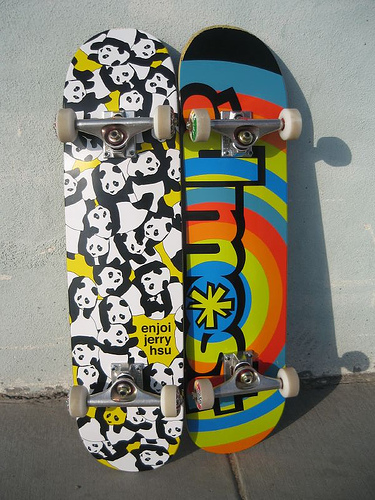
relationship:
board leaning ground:
[55, 25, 186, 473] [13, 391, 349, 498]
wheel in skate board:
[186, 107, 210, 143] [174, 15, 326, 455]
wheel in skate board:
[275, 100, 311, 145] [174, 15, 326, 455]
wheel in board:
[52, 102, 87, 147] [55, 25, 186, 473]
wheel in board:
[153, 104, 172, 140] [55, 25, 186, 473]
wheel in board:
[69, 385, 88, 418] [55, 25, 186, 473]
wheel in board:
[161, 384, 179, 416] [55, 25, 186, 473]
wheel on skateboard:
[277, 364, 300, 398] [183, 23, 289, 453]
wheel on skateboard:
[278, 107, 302, 140] [183, 23, 289, 453]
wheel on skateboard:
[186, 107, 210, 143] [183, 23, 289, 453]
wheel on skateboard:
[161, 384, 179, 416] [56, 27, 182, 471]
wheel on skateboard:
[152, 101, 173, 140] [56, 27, 182, 471]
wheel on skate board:
[184, 106, 211, 143] [175, 23, 290, 455]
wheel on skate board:
[278, 107, 302, 140] [175, 23, 290, 455]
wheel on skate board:
[193, 379, 214, 411] [175, 23, 290, 455]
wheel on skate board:
[277, 364, 300, 398] [175, 23, 290, 455]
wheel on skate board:
[153, 104, 172, 140] [60, 26, 189, 474]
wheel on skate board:
[55, 108, 77, 141] [60, 26, 189, 474]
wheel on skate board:
[69, 385, 88, 418] [60, 26, 189, 474]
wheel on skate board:
[157, 382, 182, 417] [60, 26, 189, 474]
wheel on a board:
[55, 108, 77, 141] [55, 25, 186, 473]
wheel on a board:
[153, 104, 172, 140] [55, 25, 186, 473]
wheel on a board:
[68, 385, 89, 421] [55, 25, 186, 473]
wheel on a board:
[161, 384, 179, 416] [55, 25, 186, 473]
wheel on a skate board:
[186, 107, 210, 143] [177, 26, 302, 455]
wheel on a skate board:
[278, 107, 302, 140] [177, 26, 302, 455]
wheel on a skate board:
[192, 375, 213, 413] [177, 26, 302, 455]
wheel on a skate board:
[275, 365, 298, 397] [177, 26, 302, 455]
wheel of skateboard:
[161, 384, 179, 416] [56, 27, 182, 471]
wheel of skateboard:
[278, 107, 302, 140] [171, 17, 304, 396]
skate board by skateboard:
[177, 26, 302, 455] [56, 27, 182, 471]